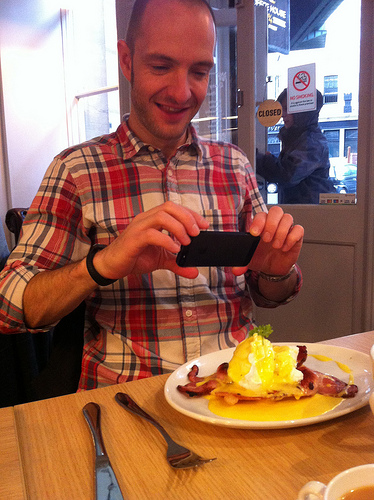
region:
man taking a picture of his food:
[0, 2, 372, 427]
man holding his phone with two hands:
[6, 0, 310, 411]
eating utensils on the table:
[72, 376, 218, 498]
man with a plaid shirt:
[0, 0, 312, 396]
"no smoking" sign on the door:
[283, 65, 324, 115]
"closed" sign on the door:
[256, 94, 285, 127]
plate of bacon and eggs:
[165, 327, 372, 434]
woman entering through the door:
[236, 0, 371, 335]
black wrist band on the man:
[80, 240, 115, 287]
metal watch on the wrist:
[259, 264, 298, 284]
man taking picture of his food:
[16, 0, 294, 355]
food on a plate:
[162, 336, 370, 431]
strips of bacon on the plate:
[166, 350, 224, 398]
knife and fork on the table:
[76, 388, 215, 496]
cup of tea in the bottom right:
[292, 459, 369, 496]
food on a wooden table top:
[3, 334, 370, 493]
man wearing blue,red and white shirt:
[0, 121, 272, 388]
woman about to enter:
[231, 76, 332, 204]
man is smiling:
[118, 4, 222, 141]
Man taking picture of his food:
[31, 5, 357, 437]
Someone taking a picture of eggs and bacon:
[69, 147, 359, 427]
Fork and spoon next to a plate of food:
[27, 360, 214, 496]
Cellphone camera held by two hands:
[111, 191, 299, 288]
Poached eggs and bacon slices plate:
[161, 311, 370, 429]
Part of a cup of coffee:
[276, 444, 372, 498]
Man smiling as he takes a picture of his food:
[70, 11, 331, 381]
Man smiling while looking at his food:
[76, 4, 373, 459]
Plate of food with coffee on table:
[161, 313, 370, 497]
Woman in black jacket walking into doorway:
[206, 32, 373, 210]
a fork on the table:
[116, 391, 214, 470]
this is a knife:
[83, 401, 121, 498]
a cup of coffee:
[302, 464, 370, 497]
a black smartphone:
[177, 230, 257, 264]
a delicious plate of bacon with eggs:
[187, 332, 348, 406]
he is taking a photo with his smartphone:
[6, 0, 296, 337]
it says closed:
[259, 102, 282, 118]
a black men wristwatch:
[85, 243, 114, 286]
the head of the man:
[120, 1, 215, 137]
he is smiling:
[111, 0, 229, 210]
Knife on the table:
[78, 396, 123, 498]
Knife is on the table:
[76, 397, 127, 498]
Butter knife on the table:
[80, 398, 127, 498]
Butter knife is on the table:
[78, 395, 129, 498]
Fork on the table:
[113, 387, 219, 474]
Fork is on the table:
[113, 385, 215, 474]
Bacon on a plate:
[179, 352, 360, 403]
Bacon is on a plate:
[179, 345, 361, 400]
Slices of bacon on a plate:
[178, 344, 359, 404]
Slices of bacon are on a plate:
[174, 341, 359, 400]